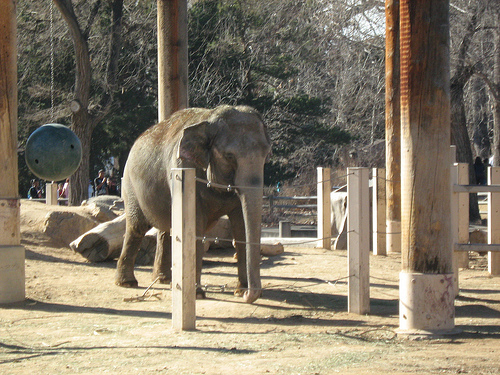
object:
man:
[93, 167, 108, 197]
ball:
[24, 120, 82, 182]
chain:
[45, 2, 58, 124]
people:
[58, 178, 67, 198]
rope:
[199, 276, 350, 290]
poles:
[166, 167, 201, 330]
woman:
[57, 176, 68, 199]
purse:
[58, 190, 67, 198]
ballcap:
[96, 168, 106, 175]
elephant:
[113, 103, 273, 303]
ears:
[175, 121, 211, 169]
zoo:
[0, 0, 483, 370]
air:
[26, 103, 132, 217]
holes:
[32, 156, 43, 166]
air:
[11, 1, 112, 121]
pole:
[396, 0, 456, 339]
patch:
[140, 102, 270, 149]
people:
[27, 180, 46, 200]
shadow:
[1, 299, 372, 326]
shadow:
[24, 246, 498, 295]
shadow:
[0, 340, 255, 360]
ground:
[1, 205, 499, 373]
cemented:
[395, 329, 455, 340]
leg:
[114, 197, 151, 288]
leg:
[195, 217, 205, 298]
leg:
[229, 204, 248, 298]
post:
[168, 166, 198, 331]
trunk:
[235, 163, 265, 303]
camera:
[99, 175, 110, 187]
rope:
[195, 233, 350, 249]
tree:
[298, 48, 383, 168]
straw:
[284, 324, 322, 340]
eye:
[220, 149, 232, 160]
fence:
[170, 167, 375, 331]